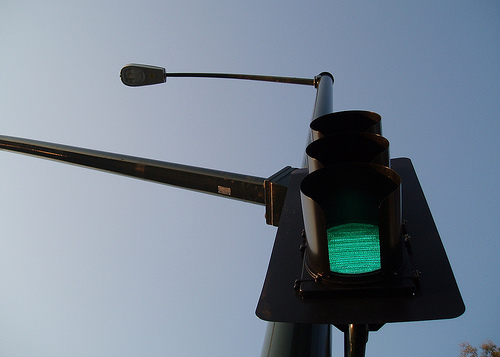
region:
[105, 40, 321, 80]
street lamp over street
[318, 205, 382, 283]
illuminated green street light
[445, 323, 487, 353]
tree in lower right corner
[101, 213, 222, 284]
clear blue sky above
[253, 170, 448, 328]
rectangle border of street light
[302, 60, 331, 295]
metal pole for street lamp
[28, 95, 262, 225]
pole on left of street lamp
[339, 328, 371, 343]
wire on bottom of lamp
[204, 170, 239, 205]
white sticker on pole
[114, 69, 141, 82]
glass bulb on lamp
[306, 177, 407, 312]
green bulb lit on traffic signal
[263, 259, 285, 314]
traffic signal is black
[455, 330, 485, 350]
part of tree in photo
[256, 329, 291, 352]
black light pole behind traffic signal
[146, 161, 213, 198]
black object projecting off pole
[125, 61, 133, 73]
bulb is unlit on pole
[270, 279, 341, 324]
black bolt in traffic signal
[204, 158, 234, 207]
white sticker on arm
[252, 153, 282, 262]
square base at pole bottom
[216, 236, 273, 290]
sky is gray and blue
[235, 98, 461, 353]
a traffic light on a pole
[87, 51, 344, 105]
a street light on a pole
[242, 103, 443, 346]
a traffic light painted black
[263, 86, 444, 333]
a traffic light with a green light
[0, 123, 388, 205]
a black post above a traffic light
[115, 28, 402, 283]
a traffic light and a street light on a pole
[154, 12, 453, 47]
a clear blue sky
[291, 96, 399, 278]
three lights on a traffic signal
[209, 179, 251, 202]
a white sticker on a pole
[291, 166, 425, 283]
a green light on a traffic light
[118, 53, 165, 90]
a streetlight that is off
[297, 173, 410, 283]
a green traffic light signal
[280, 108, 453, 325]
the housing for traffic lights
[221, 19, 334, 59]
a section of sky without clouds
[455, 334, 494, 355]
leaves on a tree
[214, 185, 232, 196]
a metal label on a pole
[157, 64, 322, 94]
the arm of a streetlight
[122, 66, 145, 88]
clear cover on a streetlight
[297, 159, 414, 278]
circular cover for an individual traffic indicator